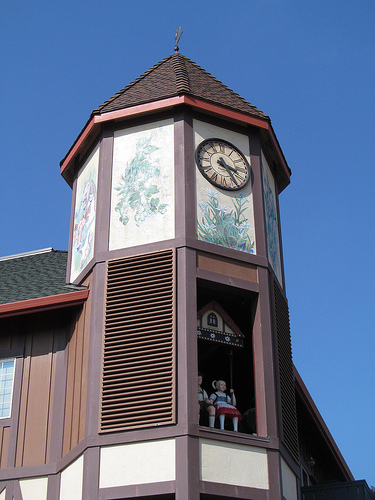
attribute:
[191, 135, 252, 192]
clock —  at top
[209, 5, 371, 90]
sky — clear, blue